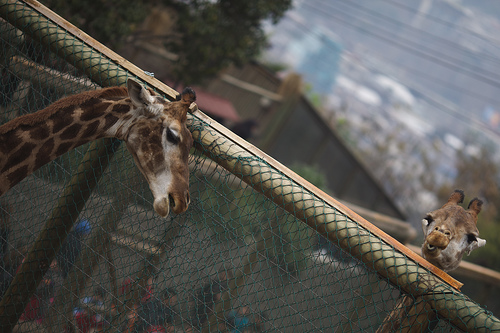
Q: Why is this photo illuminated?
A: Sunlight.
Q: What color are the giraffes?
A: Brown.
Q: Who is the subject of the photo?
A: The giraffes.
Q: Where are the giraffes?
A: By the fence.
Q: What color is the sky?
A: Blue.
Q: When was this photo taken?
A: During the day.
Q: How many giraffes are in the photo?
A: 2.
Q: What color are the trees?
A: Green.